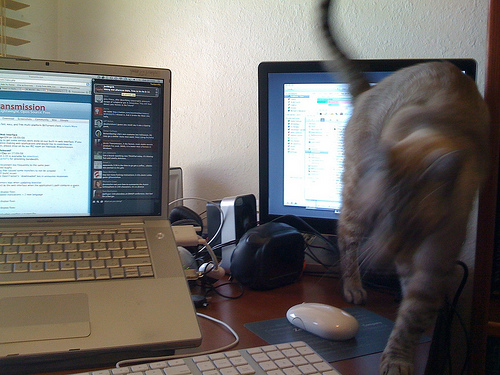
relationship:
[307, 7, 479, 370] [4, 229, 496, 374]
cat walking on desk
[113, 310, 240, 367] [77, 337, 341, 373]
cord to keyboard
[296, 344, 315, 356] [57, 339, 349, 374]
key on a keyboard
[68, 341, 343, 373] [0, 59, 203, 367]
keyboard attached to computer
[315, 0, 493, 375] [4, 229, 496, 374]
cat on desk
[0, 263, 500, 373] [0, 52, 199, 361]
desk with computer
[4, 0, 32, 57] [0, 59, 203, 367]
blinds near computer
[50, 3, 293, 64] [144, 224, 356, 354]
wall next to desk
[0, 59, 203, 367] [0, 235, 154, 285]
computer has a keyboard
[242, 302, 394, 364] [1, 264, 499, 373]
mousepad on desk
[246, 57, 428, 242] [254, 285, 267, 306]
computer on desk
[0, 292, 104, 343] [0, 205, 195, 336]
trackpad on keyboard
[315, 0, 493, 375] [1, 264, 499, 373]
cat walking on desk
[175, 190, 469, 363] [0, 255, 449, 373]
cords are on desk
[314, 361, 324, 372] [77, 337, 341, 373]
key on keyboard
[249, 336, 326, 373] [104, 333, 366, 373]
white key on keyboard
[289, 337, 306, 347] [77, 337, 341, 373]
key on keyboard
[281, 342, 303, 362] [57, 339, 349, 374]
key on keyboard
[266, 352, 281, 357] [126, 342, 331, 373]
key on keyboard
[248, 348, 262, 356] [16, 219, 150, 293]
key on keyboard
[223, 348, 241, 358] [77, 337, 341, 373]
key on keyboard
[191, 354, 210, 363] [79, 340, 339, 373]
key on key board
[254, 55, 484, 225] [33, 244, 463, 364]
computer monitor on desk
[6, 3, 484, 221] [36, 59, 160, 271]
wall behind computer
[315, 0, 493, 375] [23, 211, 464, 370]
cat on desk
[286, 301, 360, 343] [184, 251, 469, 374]
computer mouse on desk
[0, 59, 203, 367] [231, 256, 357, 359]
computer on desk